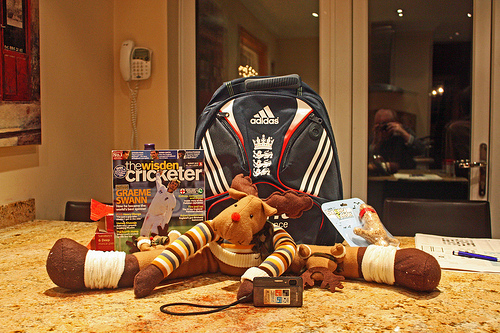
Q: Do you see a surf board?
A: No, there are no surfboards.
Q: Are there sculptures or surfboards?
A: No, there are no surfboards or sculptures.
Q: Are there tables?
A: Yes, there is a table.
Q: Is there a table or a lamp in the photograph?
A: Yes, there is a table.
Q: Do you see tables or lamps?
A: Yes, there is a table.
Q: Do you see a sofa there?
A: No, there are no sofas.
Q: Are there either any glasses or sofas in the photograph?
A: No, there are no sofas or glasses.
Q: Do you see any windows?
A: Yes, there is a window.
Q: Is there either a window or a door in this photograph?
A: Yes, there is a window.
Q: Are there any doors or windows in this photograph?
A: Yes, there is a window.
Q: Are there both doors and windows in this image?
A: Yes, there are both a window and a door.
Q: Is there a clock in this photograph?
A: No, there are no clocks.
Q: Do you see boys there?
A: No, there are no boys.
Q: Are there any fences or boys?
A: No, there are no boys or fences.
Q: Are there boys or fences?
A: No, there are no boys or fences.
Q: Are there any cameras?
A: Yes, there is a camera.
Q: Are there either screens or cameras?
A: Yes, there is a camera.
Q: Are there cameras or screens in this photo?
A: Yes, there is a camera.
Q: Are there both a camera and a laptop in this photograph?
A: No, there is a camera but no laptops.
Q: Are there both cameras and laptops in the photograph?
A: No, there is a camera but no laptops.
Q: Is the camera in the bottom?
A: Yes, the camera is in the bottom of the image.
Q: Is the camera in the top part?
A: No, the camera is in the bottom of the image.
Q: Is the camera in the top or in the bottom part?
A: The camera is in the bottom of the image.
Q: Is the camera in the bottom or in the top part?
A: The camera is in the bottom of the image.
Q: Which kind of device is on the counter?
A: The device is a camera.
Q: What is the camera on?
A: The camera is on the counter.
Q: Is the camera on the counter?
A: Yes, the camera is on the counter.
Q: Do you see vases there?
A: No, there are no vases.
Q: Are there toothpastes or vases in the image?
A: No, there are no vases or toothpastes.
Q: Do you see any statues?
A: No, there are no statues.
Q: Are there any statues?
A: No, there are no statues.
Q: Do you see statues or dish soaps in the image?
A: No, there are no statues or dish soaps.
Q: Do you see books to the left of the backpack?
A: Yes, there is a book to the left of the backpack.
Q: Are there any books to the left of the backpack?
A: Yes, there is a book to the left of the backpack.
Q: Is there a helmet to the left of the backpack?
A: No, there is a book to the left of the backpack.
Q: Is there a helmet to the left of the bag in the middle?
A: No, there is a book to the left of the backpack.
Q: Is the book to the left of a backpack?
A: Yes, the book is to the left of a backpack.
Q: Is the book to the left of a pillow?
A: No, the book is to the left of a backpack.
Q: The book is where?
A: The book is on the floor.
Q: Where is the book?
A: The book is on the floor.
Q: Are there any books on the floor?
A: Yes, there is a book on the floor.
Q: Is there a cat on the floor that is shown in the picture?
A: No, there is a book on the floor.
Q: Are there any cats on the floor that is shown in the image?
A: No, there is a book on the floor.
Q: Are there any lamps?
A: No, there are no lamps.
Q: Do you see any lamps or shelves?
A: No, there are no lamps or shelves.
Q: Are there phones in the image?
A: Yes, there is a phone.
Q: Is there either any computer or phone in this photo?
A: Yes, there is a phone.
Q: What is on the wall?
A: The phone is on the wall.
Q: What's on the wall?
A: The phone is on the wall.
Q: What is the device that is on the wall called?
A: The device is a phone.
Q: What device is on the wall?
A: The device is a phone.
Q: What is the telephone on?
A: The telephone is on the wall.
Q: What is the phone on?
A: The telephone is on the wall.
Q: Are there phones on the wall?
A: Yes, there is a phone on the wall.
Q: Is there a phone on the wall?
A: Yes, there is a phone on the wall.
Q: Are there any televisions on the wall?
A: No, there is a phone on the wall.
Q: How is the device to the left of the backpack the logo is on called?
A: The device is a phone.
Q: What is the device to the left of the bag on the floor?
A: The device is a phone.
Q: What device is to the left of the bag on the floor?
A: The device is a phone.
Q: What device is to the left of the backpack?
A: The device is a phone.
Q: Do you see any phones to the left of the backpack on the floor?
A: Yes, there is a phone to the left of the backpack.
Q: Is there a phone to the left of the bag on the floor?
A: Yes, there is a phone to the left of the backpack.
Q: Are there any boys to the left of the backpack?
A: No, there is a phone to the left of the backpack.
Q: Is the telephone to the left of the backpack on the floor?
A: Yes, the telephone is to the left of the backpack.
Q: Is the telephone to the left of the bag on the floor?
A: Yes, the telephone is to the left of the backpack.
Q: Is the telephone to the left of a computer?
A: No, the telephone is to the left of the backpack.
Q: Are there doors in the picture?
A: Yes, there is a door.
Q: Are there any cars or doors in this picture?
A: Yes, there is a door.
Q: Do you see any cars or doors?
A: Yes, there is a door.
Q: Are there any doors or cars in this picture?
A: Yes, there is a door.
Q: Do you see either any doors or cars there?
A: Yes, there is a door.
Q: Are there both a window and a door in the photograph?
A: Yes, there are both a door and a window.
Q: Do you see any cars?
A: No, there are no cars.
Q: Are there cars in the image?
A: No, there are no cars.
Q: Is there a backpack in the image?
A: Yes, there is a backpack.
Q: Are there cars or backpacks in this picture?
A: Yes, there is a backpack.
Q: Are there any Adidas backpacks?
A: Yes, there is an Adidas backpack.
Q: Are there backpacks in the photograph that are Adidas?
A: Yes, there is a backpack that is adidas.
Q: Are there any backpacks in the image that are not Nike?
A: Yes, there is a Adidas backpack.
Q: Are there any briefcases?
A: No, there are no briefcases.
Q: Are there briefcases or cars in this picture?
A: No, there are no briefcases or cars.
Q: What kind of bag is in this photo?
A: The bag is a backpack.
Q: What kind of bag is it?
A: The bag is a backpack.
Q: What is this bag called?
A: That is a backpack.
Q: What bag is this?
A: That is a backpack.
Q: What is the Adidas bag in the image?
A: The bag is a backpack.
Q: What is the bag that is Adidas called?
A: The bag is a backpack.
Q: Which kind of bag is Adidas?
A: The bag is a backpack.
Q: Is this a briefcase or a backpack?
A: This is a backpack.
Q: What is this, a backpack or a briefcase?
A: This is a backpack.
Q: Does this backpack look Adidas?
A: Yes, the backpack is adidas.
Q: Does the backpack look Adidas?
A: Yes, the backpack is adidas.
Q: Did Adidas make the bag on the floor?
A: Yes, the backpack was made by adidas.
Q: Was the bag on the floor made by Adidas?
A: Yes, the backpack was made by adidas.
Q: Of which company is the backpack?
A: The backpack is adidas.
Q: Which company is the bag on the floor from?
A: The backpack is from adidas.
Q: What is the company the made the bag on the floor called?
A: The company is adidas.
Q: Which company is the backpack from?
A: The backpack is from adidas.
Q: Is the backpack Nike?
A: No, the backpack is adidas.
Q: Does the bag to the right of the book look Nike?
A: No, the backpack is adidas.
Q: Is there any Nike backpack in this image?
A: No, there is a backpack but it is adidas.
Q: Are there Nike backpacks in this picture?
A: No, there is a backpack but it is adidas.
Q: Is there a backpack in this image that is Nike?
A: No, there is a backpack but it is adidas.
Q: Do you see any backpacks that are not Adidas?
A: No, there is a backpack but it is adidas.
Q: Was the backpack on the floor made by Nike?
A: No, the backpack was made by adidas.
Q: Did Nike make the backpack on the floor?
A: No, the backpack was made by adidas.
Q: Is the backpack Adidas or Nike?
A: The backpack is adidas.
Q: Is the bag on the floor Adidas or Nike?
A: The backpack is adidas.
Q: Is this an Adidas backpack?
A: Yes, this is an Adidas backpack.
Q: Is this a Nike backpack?
A: No, this is an Adidas backpack.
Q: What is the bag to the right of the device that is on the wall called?
A: The bag is a backpack.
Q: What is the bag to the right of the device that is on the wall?
A: The bag is a backpack.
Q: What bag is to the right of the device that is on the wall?
A: The bag is a backpack.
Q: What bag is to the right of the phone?
A: The bag is a backpack.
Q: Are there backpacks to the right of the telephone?
A: Yes, there is a backpack to the right of the telephone.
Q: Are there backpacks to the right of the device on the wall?
A: Yes, there is a backpack to the right of the telephone.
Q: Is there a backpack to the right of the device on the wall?
A: Yes, there is a backpack to the right of the telephone.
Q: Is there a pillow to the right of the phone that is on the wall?
A: No, there is a backpack to the right of the telephone.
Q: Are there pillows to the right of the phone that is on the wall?
A: No, there is a backpack to the right of the telephone.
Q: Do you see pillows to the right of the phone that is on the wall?
A: No, there is a backpack to the right of the telephone.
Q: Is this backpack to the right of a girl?
A: No, the backpack is to the right of the telephone.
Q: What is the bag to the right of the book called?
A: The bag is a backpack.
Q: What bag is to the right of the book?
A: The bag is a backpack.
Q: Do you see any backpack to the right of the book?
A: Yes, there is a backpack to the right of the book.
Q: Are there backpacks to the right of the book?
A: Yes, there is a backpack to the right of the book.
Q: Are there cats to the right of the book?
A: No, there is a backpack to the right of the book.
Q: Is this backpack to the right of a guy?
A: No, the backpack is to the right of a book.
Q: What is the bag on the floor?
A: The bag is a backpack.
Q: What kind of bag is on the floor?
A: The bag is a backpack.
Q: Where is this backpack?
A: The backpack is on the floor.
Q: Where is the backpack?
A: The backpack is on the floor.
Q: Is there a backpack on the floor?
A: Yes, there is a backpack on the floor.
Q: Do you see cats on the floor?
A: No, there is a backpack on the floor.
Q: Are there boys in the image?
A: No, there are no boys.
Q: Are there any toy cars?
A: No, there are no toy cars.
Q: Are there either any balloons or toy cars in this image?
A: No, there are no toy cars or balloons.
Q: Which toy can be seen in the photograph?
A: The toy is a stuffed animal.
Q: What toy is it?
A: The toy is a stuffed animal.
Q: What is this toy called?
A: This is a stuffed animal.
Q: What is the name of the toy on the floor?
A: The toy is a stuffed animal.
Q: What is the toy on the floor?
A: The toy is a stuffed animal.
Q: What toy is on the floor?
A: The toy is a stuffed animal.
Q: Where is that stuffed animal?
A: The stuffed animal is on the floor.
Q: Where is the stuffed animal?
A: The stuffed animal is on the floor.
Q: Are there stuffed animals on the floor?
A: Yes, there is a stuffed animal on the floor.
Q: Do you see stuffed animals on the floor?
A: Yes, there is a stuffed animal on the floor.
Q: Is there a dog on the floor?
A: No, there is a stuffed animal on the floor.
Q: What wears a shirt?
A: The stuffed animal wears a shirt.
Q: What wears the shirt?
A: The stuffed animal wears a shirt.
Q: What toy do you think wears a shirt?
A: The toy is a stuffed animal.